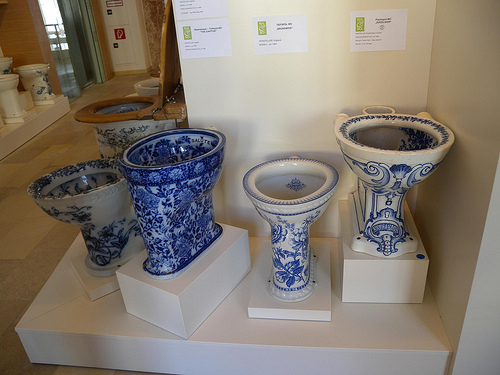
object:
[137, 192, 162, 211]
flowers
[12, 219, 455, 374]
platform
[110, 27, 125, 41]
sign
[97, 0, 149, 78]
wall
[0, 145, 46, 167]
tile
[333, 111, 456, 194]
bowl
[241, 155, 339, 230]
bowl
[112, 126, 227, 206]
bowl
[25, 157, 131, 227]
bowl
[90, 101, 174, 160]
bowl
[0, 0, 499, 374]
showroom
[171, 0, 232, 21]
signs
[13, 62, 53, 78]
toilet bowels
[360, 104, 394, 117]
cup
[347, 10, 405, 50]
paper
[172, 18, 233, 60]
paper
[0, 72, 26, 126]
toilets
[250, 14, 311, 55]
paper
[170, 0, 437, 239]
wall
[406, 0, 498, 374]
wall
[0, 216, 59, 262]
tiles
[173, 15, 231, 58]
piece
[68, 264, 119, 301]
platform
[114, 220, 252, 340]
platform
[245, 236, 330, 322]
platform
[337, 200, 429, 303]
platform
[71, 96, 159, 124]
seat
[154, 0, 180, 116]
wood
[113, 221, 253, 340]
box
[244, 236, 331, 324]
box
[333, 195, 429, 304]
box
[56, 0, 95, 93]
doors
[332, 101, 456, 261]
toilet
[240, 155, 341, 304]
toilet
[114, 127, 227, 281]
toilet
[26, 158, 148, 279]
toilet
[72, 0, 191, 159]
toilet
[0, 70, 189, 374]
floor